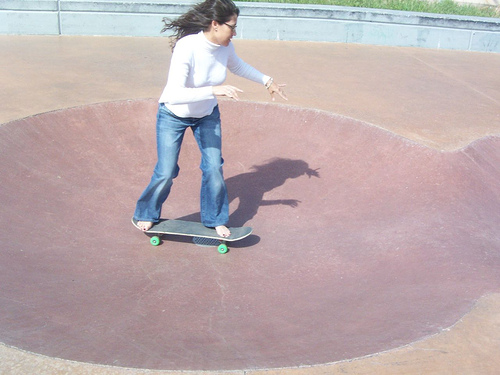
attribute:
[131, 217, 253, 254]
skateboard — wooden, black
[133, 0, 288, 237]
woman — riding, barefoot, skateboarding, brunette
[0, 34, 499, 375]
ground — brown, concrete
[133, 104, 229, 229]
jeans — blue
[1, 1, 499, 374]
skatepark — cement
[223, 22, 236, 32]
glasses — black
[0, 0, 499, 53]
fence — concrete, grey, short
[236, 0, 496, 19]
leaves — green, short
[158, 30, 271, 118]
sweater — white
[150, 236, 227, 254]
wheels — green, mint green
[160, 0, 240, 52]
hair — black, brunette